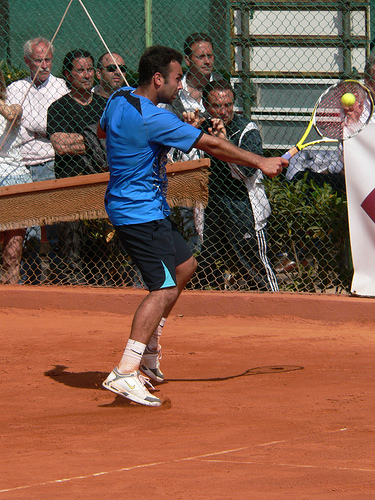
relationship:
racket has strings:
[278, 77, 372, 162] [327, 94, 351, 121]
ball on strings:
[340, 92, 356, 108] [327, 94, 351, 121]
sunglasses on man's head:
[103, 63, 129, 77] [92, 44, 148, 115]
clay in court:
[113, 421, 239, 491] [0, 283, 375, 499]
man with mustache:
[34, 66, 52, 72] [5, 37, 76, 175]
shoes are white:
[114, 336, 178, 462] [135, 387, 148, 399]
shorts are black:
[111, 207, 192, 293] [140, 248, 155, 270]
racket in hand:
[281, 77, 375, 165] [258, 154, 292, 175]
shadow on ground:
[36, 342, 323, 429] [129, 441, 201, 484]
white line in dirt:
[2, 423, 371, 492] [58, 454, 111, 499]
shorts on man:
[125, 262, 183, 292] [46, 18, 374, 483]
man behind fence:
[7, 35, 72, 186] [2, 0, 370, 301]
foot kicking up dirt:
[99, 363, 163, 406] [159, 385, 178, 417]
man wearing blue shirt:
[103, 47, 195, 409] [103, 90, 182, 220]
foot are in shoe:
[100, 363, 164, 407] [102, 369, 167, 412]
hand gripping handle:
[253, 154, 295, 181] [248, 137, 299, 198]